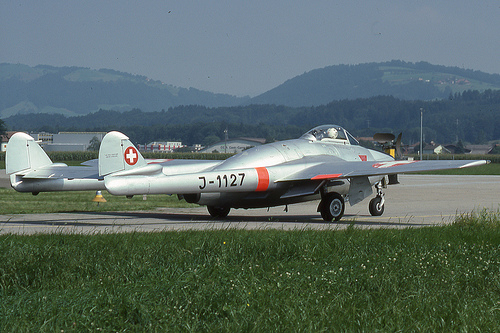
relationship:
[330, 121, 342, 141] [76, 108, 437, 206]
pilot on plane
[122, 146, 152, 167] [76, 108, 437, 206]
circle on plane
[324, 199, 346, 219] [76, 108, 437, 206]
wheel on plane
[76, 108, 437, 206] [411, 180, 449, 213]
plane on runway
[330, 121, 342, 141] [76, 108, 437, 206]
pilot in plane